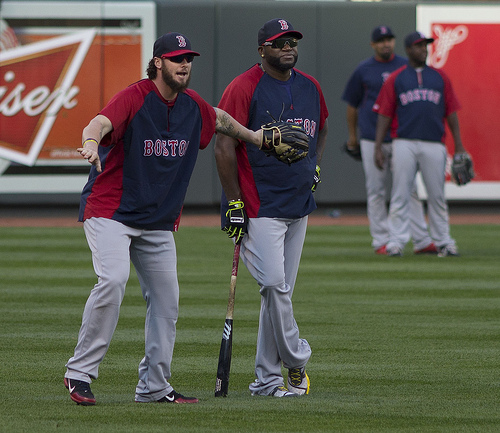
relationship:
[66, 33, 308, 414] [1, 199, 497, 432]
man standing on field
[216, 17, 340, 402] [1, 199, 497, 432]
man standing on field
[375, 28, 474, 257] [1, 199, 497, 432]
man standing on field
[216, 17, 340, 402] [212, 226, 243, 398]
man leaning on a bat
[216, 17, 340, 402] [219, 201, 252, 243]
man wearing gloves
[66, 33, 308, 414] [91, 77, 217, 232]
man wearing a jersey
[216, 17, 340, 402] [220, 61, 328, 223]
man wearing a jersey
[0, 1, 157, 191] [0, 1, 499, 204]
sign on wall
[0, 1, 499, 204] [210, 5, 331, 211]
wall has panels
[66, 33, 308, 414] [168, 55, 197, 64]
man wearing sunglasses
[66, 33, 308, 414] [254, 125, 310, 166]
man wearing a mitt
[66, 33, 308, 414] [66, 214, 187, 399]
man wearing pants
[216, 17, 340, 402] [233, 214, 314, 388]
man wearing pants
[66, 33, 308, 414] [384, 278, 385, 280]
man playing baseball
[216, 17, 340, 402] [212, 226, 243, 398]
man holding bat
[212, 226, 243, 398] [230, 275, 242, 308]
bat made of wood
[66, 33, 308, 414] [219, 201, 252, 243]
man wearing gloves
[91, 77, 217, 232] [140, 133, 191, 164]
jersey says boston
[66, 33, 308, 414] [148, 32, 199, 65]
man wearing baseball hat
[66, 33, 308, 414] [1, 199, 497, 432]
man on field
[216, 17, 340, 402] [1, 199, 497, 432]
man on field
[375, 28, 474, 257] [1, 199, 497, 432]
man on field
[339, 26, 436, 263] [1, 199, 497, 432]
player on field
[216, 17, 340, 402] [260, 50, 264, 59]
man has an earring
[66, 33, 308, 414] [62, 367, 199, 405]
man wearing shoes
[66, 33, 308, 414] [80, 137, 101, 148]
man wearing a bracelet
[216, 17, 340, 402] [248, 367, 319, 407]
man wearing sneakers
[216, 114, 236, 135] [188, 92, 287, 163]
tattoo on h arm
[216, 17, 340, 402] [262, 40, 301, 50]
man wearing sunglasses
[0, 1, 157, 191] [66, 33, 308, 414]
sign behind man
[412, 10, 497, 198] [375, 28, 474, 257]
sign behind man